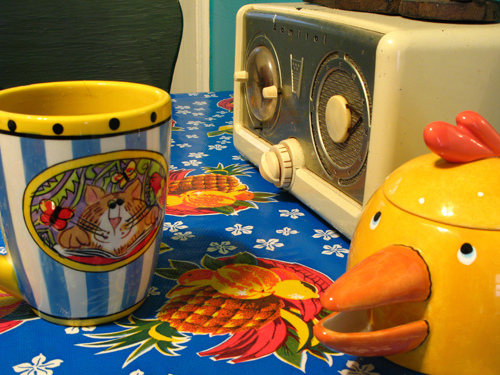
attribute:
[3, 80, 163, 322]
coffee mug — colorful, blue and white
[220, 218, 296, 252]
white flowers — small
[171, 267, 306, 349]
pineapple — orange, yellow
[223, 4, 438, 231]
timer — large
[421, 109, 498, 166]
feather — orange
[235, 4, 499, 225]
radio — old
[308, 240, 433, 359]
nose — orange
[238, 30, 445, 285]
toaster — white and metal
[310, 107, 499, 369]
chicken head — orange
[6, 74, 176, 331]
mug — coffee mug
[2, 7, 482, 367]
area — kitchen area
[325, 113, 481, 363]
head — chicken head, yellow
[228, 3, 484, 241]
radio — old-fashioned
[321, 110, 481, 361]
cookie jar —  chicken-like 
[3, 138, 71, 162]
strips — blue, white